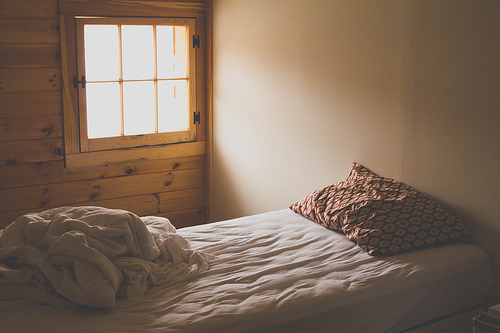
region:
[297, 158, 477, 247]
printed pillow on bed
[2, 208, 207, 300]
crumpled and rumpled bedding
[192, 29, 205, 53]
black hinge on window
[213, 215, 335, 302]
wrinkled mattress covering on bed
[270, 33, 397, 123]
light colored wall in room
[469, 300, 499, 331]
corner edge of an object sticking out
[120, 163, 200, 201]
portion of the wood wall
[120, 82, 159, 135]
a pane in the window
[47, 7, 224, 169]
window in bedroom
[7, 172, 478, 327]
bed with sheets and pillow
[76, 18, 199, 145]
Window with six smaller window panels.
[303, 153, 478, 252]
Patterned pillow case on top of the bed.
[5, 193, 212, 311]
Crumpled up white blanket on the bed.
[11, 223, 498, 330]
White fitted sheet on the bed.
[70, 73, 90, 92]
Middle clasp on the left side of the window.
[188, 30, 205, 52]
Top metal window hinge on the window frame.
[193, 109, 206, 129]
Bottom metal clasp on the bottom of the window frame.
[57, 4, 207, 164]
Wooden square shape around the window.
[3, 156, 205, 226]
Wood panels below the window.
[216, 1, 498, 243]
Beige wall the bed is up against.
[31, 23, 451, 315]
a small personal bedroom.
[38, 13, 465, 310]
a cozy personal bedroom.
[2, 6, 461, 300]
a single personal bedroom.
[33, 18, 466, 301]
personal bedroom with daylight shining through.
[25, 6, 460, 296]
a personal bedroom with small bed.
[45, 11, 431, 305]
a personal room with bed and a window.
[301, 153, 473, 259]
pillow to a bed.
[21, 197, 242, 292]
white bedsheets appearing used.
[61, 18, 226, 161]
window to a room.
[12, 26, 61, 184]
wooden walls to a room.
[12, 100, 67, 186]
the wall is brown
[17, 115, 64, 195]
the wall is made of wood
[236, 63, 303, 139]
the wall is beige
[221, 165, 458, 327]
the pillow is on the bed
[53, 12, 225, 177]
the window is closed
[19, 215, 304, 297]
the blanket is white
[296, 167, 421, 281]
the pillow is rectangle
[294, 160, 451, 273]
the pillow is brown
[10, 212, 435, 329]
the bed is rectangle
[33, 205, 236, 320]
the blanket is rumpled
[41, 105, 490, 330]
unmade bed with white sheet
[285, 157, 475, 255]
pillow at head of bed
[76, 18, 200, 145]
sun shining through window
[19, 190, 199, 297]
white blanket in a pile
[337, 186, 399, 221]
wrinkled print case on pillow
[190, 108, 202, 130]
black metal hardware on window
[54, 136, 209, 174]
wood sill under window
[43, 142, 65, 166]
knots in wood wall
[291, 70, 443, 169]
plain white wall behind bed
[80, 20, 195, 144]
six panes in window